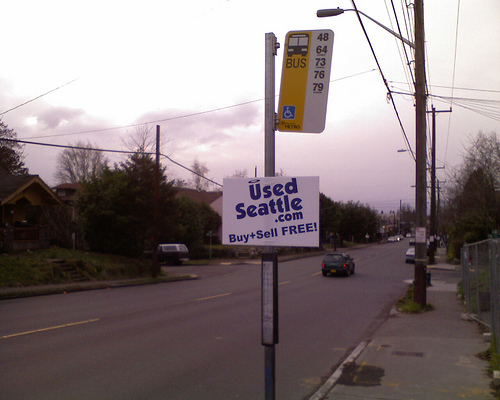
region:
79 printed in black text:
[310, 80, 324, 92]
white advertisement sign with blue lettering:
[223, 176, 318, 246]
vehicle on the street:
[320, 251, 362, 276]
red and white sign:
[416, 227, 426, 242]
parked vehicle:
[155, 243, 191, 267]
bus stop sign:
[281, 30, 330, 130]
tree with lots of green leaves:
[78, 170, 150, 259]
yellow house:
[2, 174, 60, 254]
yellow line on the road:
[1, 315, 106, 340]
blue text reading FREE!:
[279, 222, 318, 236]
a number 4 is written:
[316, 31, 323, 41]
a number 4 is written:
[322, 45, 329, 54]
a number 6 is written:
[316, 43, 322, 56]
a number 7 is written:
[311, 67, 318, 79]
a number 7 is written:
[310, 81, 317, 89]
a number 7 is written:
[314, 53, 321, 68]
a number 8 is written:
[323, 30, 332, 40]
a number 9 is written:
[315, 76, 325, 93]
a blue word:
[243, 175, 300, 200]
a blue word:
[233, 192, 300, 224]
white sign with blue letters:
[173, 166, 356, 300]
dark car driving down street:
[287, 209, 364, 334]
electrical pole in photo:
[57, 120, 198, 236]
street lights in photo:
[354, 66, 467, 281]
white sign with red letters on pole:
[396, 211, 442, 296]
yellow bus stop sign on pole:
[270, 41, 341, 139]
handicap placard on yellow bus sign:
[229, 39, 357, 152]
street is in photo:
[97, 254, 289, 398]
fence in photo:
[437, 219, 485, 396]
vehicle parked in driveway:
[136, 205, 218, 335]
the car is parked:
[122, 224, 200, 273]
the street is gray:
[86, 289, 252, 389]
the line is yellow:
[29, 307, 134, 344]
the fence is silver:
[453, 239, 497, 354]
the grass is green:
[388, 296, 435, 318]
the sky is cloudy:
[96, 37, 239, 163]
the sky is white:
[110, 45, 249, 125]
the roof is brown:
[5, 170, 71, 230]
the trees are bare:
[52, 141, 147, 200]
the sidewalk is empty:
[378, 234, 472, 399]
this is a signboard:
[223, 178, 320, 245]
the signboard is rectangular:
[216, 171, 321, 251]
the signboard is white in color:
[228, 180, 240, 199]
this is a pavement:
[393, 320, 473, 392]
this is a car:
[321, 249, 353, 276]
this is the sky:
[100, 46, 180, 94]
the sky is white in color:
[63, 28, 176, 88]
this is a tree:
[69, 146, 159, 260]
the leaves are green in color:
[96, 180, 121, 226]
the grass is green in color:
[0, 250, 30, 279]